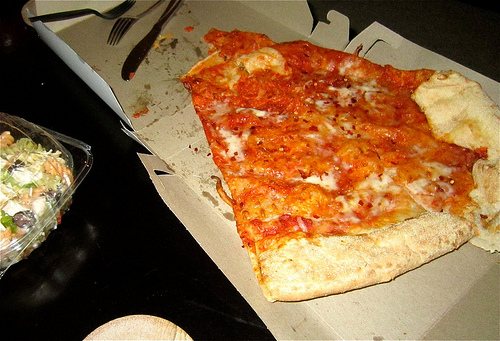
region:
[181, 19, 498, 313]
this is a pizza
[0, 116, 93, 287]
a salad in a box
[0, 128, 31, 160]
there are twisty noodles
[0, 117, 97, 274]
there is pasta in the salad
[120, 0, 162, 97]
this is a knife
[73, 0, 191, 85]
these are utensils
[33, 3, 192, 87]
these are eating utensils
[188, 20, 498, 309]
the lives of pizza are large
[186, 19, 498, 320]
the pizza is on a cardboard box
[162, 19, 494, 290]
a cooked piece of pizza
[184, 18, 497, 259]
a large slice of pizza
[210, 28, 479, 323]
a large sliced piece of pizza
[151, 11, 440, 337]
a large baked slice of pizza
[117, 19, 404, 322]
pizza on a cardboard box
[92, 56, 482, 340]
a pizza on the table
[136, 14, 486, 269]
a slice of pizza on the table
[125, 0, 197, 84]
A small silver knife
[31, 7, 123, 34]
A small silver knife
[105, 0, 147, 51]
A small silver fork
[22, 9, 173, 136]
A white paper box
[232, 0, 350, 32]
A white paper box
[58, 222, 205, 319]
A black table surface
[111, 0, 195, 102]
knife in the box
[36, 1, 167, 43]
forks in the box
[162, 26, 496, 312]
pizza is on the box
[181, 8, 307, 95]
slice is folded at the end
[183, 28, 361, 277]
cheese pizza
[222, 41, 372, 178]
crushed pepper on the pizza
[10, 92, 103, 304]
salad next to the pizza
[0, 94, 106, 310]
salad in a plastic container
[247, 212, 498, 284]
crust of the pizza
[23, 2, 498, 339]
pizza box is on the table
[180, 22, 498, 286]
A slice of cheese pizza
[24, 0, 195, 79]
A set of utensils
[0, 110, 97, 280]
A small salad mix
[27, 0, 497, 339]
A pizza box with pizza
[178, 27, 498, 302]
A slice of pizza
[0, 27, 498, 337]
A pizza and salad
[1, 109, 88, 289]
Salad in a small container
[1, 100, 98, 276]
Salad in a package on the table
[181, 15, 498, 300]
A slice of bitten pizza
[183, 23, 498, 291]
A large pizza slice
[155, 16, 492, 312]
a slice of pizza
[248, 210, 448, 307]
crust on the pizza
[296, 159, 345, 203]
white cheese on pizza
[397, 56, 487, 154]
crust is folded over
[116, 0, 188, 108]
knife in a box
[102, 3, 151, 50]
fork on a box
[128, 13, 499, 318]
pizza on the box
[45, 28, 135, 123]
white trim on box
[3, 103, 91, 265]
salad on the side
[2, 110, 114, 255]
a clear plastic container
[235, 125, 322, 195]
Sauce on a piece of pizza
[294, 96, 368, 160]
Sauce on a piece of pizza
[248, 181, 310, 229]
Sauce on a piece of pizza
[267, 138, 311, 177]
Sauce on a piece of pizza